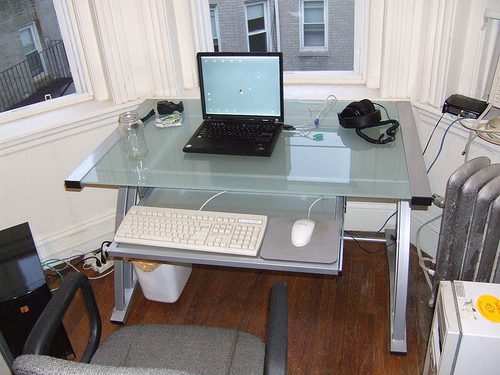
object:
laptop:
[181, 50, 285, 157]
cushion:
[89, 323, 269, 373]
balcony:
[0, 38, 74, 112]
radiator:
[431, 155, 500, 294]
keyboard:
[113, 205, 269, 257]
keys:
[139, 234, 172, 243]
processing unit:
[421, 280, 500, 375]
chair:
[11, 272, 290, 375]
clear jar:
[117, 110, 149, 161]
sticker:
[476, 294, 500, 324]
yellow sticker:
[476, 293, 499, 323]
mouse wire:
[307, 196, 324, 219]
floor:
[2, 228, 444, 373]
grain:
[66, 231, 436, 372]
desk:
[61, 98, 435, 356]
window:
[208, 0, 356, 72]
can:
[131, 261, 193, 304]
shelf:
[108, 188, 346, 277]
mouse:
[290, 218, 316, 247]